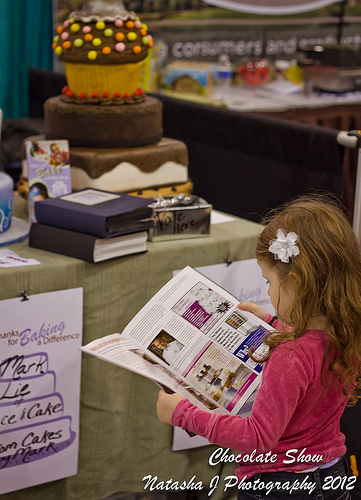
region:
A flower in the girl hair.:
[264, 225, 301, 269]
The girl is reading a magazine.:
[114, 300, 290, 426]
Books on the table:
[41, 185, 145, 266]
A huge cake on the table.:
[57, 8, 179, 183]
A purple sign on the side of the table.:
[10, 286, 106, 488]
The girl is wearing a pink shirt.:
[215, 341, 342, 456]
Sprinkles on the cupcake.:
[62, 18, 136, 53]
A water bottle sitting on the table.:
[210, 36, 233, 103]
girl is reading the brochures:
[95, 208, 328, 495]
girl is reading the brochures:
[97, 210, 358, 476]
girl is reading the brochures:
[108, 212, 335, 453]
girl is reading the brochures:
[95, 200, 330, 495]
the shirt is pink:
[158, 330, 356, 461]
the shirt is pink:
[174, 317, 357, 475]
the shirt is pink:
[202, 324, 357, 498]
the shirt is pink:
[181, 304, 352, 498]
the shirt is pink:
[176, 314, 343, 484]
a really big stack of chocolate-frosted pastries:
[16, 7, 195, 207]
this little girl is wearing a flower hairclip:
[265, 226, 302, 264]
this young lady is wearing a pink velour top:
[168, 311, 360, 482]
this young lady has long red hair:
[252, 189, 359, 406]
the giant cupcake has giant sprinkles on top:
[49, 8, 158, 107]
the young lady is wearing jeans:
[234, 458, 357, 499]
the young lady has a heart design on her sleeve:
[190, 407, 217, 439]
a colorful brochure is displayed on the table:
[21, 132, 73, 224]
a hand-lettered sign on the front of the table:
[0, 283, 86, 496]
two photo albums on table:
[37, 173, 156, 261]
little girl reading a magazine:
[208, 194, 341, 486]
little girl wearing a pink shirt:
[187, 206, 347, 482]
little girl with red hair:
[199, 207, 353, 486]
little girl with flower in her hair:
[203, 203, 355, 491]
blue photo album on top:
[30, 174, 149, 228]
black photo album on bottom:
[30, 215, 139, 266]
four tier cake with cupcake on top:
[37, 7, 220, 209]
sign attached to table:
[1, 290, 94, 479]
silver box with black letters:
[154, 191, 216, 250]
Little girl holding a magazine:
[76, 189, 358, 455]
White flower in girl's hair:
[263, 222, 306, 270]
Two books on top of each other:
[25, 180, 159, 267]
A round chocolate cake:
[39, 90, 167, 151]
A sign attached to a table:
[1, 285, 86, 497]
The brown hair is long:
[246, 192, 358, 408]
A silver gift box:
[142, 186, 216, 244]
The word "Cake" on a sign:
[25, 395, 69, 424]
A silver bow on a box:
[147, 186, 196, 211]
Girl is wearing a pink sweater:
[168, 188, 358, 482]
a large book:
[79, 267, 281, 417]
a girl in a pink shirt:
[171, 201, 359, 493]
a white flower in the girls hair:
[270, 227, 300, 262]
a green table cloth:
[2, 193, 298, 497]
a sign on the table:
[3, 296, 80, 490]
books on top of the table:
[33, 193, 151, 258]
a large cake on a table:
[44, 20, 193, 202]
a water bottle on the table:
[214, 54, 230, 99]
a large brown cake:
[36, 4, 192, 204]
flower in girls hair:
[270, 226, 298, 261]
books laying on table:
[27, 184, 163, 265]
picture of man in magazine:
[147, 328, 185, 363]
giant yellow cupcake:
[50, 9, 161, 103]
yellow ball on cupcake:
[86, 48, 98, 59]